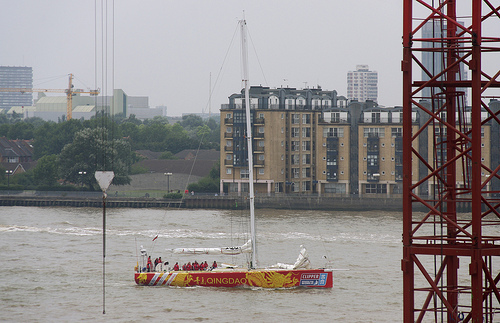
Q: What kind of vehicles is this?
A: Boat.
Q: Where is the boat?
A: Body of water.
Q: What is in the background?
A: Buildings.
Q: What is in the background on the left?
A: Trees.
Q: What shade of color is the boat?
A: Red and yellow.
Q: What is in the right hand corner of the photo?
A: Red metal tall tower railing.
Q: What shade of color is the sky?
A: Grey.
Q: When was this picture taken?
A: This picture was taken in the day time.